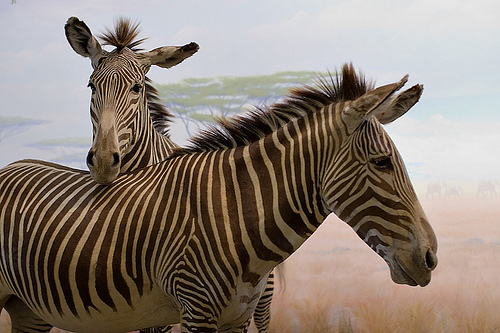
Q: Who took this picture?
A: A tourist.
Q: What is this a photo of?
A: Zebras.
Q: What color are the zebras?
A: Black and white.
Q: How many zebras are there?
A: Two.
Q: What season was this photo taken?
A: Fall.